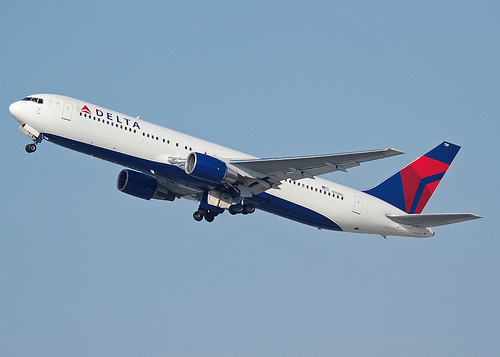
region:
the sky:
[164, 210, 289, 333]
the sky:
[250, 271, 297, 316]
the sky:
[254, 286, 298, 354]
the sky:
[254, 265, 325, 344]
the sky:
[226, 241, 304, 353]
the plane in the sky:
[7, 79, 485, 236]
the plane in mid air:
[7, 80, 483, 248]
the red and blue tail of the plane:
[370, 142, 457, 214]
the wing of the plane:
[217, 135, 399, 195]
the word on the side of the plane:
[92, 106, 142, 131]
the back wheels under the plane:
[190, 195, 256, 227]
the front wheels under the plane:
[23, 140, 38, 152]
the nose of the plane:
[3, 97, 18, 112]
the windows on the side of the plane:
[77, 112, 344, 205]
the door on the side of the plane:
[59, 98, 74, 122]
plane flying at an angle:
[10, 68, 483, 281]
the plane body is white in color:
[6, 79, 476, 244]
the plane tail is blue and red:
[360, 123, 462, 213]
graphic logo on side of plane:
[77, 101, 145, 133]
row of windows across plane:
[75, 111, 355, 211]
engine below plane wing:
[182, 150, 270, 203]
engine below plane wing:
[116, 163, 200, 204]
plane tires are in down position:
[189, 194, 257, 220]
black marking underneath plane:
[35, 128, 351, 237]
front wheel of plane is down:
[22, 133, 44, 154]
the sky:
[220, 264, 257, 350]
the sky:
[279, 287, 325, 352]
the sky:
[284, 303, 305, 345]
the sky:
[271, 317, 323, 349]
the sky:
[297, 262, 330, 342]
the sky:
[300, 319, 339, 349]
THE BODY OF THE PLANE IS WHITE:
[5, 87, 482, 239]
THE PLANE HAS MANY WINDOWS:
[76, 109, 346, 203]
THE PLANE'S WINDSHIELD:
[21, 94, 43, 107]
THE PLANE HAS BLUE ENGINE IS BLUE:
[182, 149, 231, 192]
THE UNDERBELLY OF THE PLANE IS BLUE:
[41, 130, 343, 235]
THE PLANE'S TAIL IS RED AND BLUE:
[360, 130, 460, 227]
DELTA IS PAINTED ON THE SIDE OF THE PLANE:
[95, 105, 140, 131]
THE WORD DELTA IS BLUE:
[78, 104, 141, 134]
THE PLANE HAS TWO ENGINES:
[112, 152, 234, 221]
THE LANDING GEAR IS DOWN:
[187, 190, 276, 240]